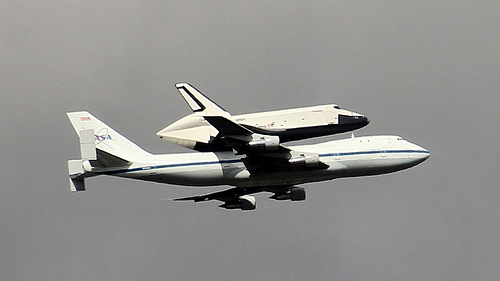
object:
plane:
[60, 109, 432, 210]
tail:
[63, 110, 148, 163]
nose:
[418, 143, 432, 166]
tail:
[174, 81, 226, 119]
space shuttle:
[154, 81, 369, 151]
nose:
[354, 111, 370, 129]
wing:
[202, 114, 252, 135]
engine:
[284, 153, 330, 172]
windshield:
[395, 137, 401, 141]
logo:
[92, 129, 112, 145]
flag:
[80, 116, 92, 122]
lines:
[175, 85, 205, 114]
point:
[155, 125, 176, 142]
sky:
[0, 0, 499, 121]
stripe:
[94, 149, 430, 171]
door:
[380, 142, 394, 155]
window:
[333, 104, 341, 109]